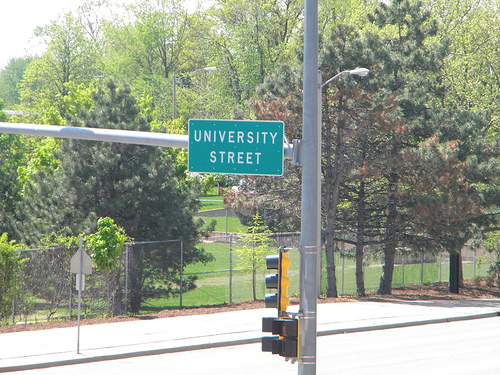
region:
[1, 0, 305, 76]
The sky is white.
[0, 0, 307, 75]
The sky is clear.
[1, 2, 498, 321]
The trees are green.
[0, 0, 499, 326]
The trees have leaves.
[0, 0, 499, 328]
Trees are in the background.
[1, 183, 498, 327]
The grass is green.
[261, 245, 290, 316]
A traffic light.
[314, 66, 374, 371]
A street lamp.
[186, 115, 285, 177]
A street sign.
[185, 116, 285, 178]
The street sign is made of metal.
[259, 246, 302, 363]
A traffic light.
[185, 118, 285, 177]
A street sign reads "University Street".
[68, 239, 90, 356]
A sign on a metal pole.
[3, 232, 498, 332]
A chain-link fence runs along the street.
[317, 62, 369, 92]
A street light.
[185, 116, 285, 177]
The street sign is green with white letters.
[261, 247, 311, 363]
The traffic signal is yellow and black.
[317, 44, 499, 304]
A row of trees along the sidewalk.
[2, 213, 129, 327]
Ivy is growing on the fence.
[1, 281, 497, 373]
The sidewalk is empty.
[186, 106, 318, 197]
green and white sign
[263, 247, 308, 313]
yellow and black traffic sign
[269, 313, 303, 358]
two pedestrian walk signals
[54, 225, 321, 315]
grey chain link fence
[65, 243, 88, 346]
reverse side of school sign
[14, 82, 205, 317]
green trees behind fence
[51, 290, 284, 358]
school sign on sidewalk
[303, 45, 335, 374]
traffic sign on dark grey pole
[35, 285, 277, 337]
dark brown pine straw under trees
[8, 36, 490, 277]
tall trees behind field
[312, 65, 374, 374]
A light post.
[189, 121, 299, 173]
green university street sign on pole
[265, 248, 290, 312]
black and yellow street light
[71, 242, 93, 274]
back side of school zone sign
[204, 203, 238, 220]
parking lot in the distance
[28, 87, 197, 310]
tall evergreen tree behind fence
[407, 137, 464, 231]
tree leave turning in fall season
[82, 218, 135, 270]
climbing vines growing on metal fence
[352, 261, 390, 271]
walking track behind metal fence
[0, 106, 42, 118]
grey roof of building in distance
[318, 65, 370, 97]
metal and glass street lamp on pole